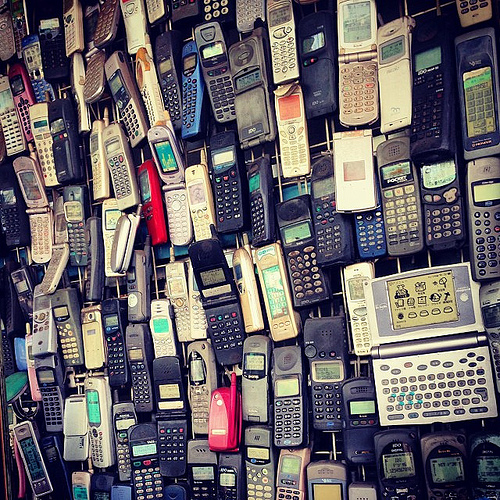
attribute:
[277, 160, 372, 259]
cell phone — black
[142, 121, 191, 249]
phone — flip phone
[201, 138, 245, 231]
cellphone — cell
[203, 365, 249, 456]
phone — red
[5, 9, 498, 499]
cellphones — cell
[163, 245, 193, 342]
phone — silver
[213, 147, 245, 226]
cell phone — black, hanging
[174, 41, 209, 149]
handset — blue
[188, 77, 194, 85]
button — black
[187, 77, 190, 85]
button — black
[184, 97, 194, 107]
button — black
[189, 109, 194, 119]
button — black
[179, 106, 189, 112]
button — black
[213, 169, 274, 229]
buttons — black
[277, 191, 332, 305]
phone — black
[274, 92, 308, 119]
screen — bright orange, phone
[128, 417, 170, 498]
cellphone — black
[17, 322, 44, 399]
cellphone — pink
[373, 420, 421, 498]
cell phone — black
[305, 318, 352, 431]
cellphone — black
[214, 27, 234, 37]
wire hook — white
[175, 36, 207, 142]
cell phone — blue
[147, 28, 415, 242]
cell phone — black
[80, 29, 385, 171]
cell phone — hanging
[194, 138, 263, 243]
cell phone — pink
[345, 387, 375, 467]
phone — black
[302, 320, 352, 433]
phone — cell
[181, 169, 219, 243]
phone — cell